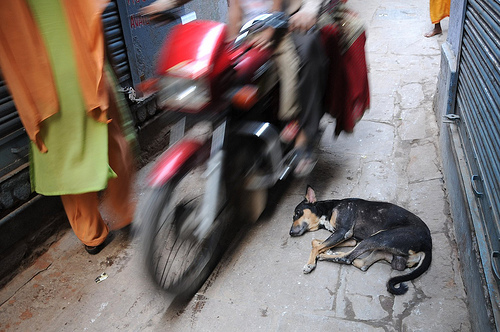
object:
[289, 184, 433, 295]
dog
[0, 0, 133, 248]
outfit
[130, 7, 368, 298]
motorcycle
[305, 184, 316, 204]
ear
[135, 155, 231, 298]
wheel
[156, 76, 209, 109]
light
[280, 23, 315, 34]
handle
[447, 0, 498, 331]
door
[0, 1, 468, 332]
ground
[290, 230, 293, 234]
nose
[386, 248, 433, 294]
tail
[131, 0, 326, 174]
man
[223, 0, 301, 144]
child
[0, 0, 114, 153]
scarf